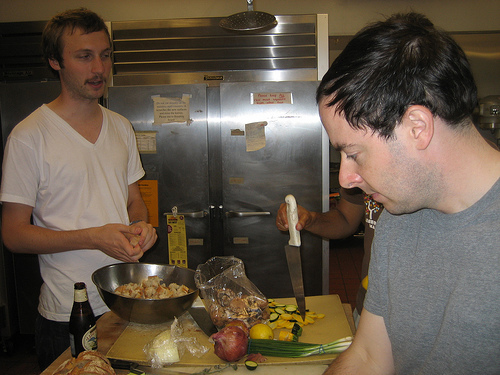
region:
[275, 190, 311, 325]
knife with a white handle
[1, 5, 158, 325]
man wearing a white shirt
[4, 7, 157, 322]
male wearing a white shirt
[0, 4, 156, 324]
male wearing a white tshirt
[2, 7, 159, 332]
man wearing a white shirt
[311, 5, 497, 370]
man wearing a grey shirt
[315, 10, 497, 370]
man wearing a grey tshirt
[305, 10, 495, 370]
male wearing a grey shirt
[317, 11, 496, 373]
male wearing a grey tshirt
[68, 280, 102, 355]
a bottle of beer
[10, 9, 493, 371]
guys preparing food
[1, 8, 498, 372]
guys in the kitchen preparing food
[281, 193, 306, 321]
a knife with white handle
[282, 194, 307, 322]
a knife the guy is holding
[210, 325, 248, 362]
a red onion on the table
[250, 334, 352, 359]
a bundle of spring onions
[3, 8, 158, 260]
a guy wearing white shirt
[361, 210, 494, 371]
a gray shirt the guy is wearing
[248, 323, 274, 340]
a lemon on the table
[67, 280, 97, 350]
a bottle on the table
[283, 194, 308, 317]
large kitchen knife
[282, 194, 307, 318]
large knife with white handle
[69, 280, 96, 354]
bottle of bear on the counter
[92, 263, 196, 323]
metal, silver bowl on counter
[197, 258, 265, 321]
plastic bag with concussion on the counter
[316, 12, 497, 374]
man on the right in gray shirt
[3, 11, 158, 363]
man in white shirt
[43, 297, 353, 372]
counter with ingredients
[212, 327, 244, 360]
large onion on the counter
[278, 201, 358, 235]
hand holding knife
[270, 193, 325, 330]
a white handled knife being stuck into the table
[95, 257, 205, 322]
a metal bowl with breadcrumbs inside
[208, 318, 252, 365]
two red onions with the skin on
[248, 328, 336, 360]
a small bunch of green onions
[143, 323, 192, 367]
a white onion wrapped in plastic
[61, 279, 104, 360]
an open bottle of beer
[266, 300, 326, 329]
sliced vegetables on the table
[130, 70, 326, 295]
metal commercial refrigerator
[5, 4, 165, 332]
man wearing a white shirt.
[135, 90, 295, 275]
several notes taped to refrigerater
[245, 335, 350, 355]
green onions tied with rubber band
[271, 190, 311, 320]
hand hold a chopping knife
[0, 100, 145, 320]
white v-necked t-shirt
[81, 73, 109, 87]
mustache on man's face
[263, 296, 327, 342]
chopped pieces of green and yellow squash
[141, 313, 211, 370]
vegetable item wrapped in cellophane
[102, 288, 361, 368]
beige chopping board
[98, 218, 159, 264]
hands holding food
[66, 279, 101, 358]
brown bottle with label